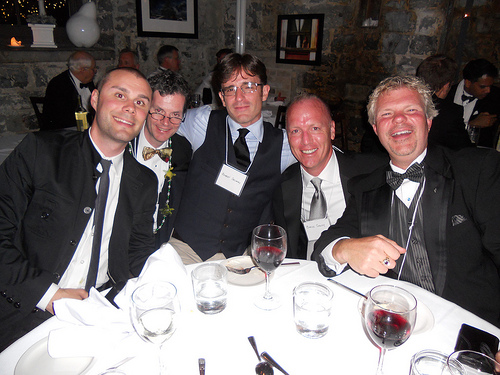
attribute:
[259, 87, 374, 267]
man — balding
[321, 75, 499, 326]
man — smiling,  blonde 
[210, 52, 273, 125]
hair — brown.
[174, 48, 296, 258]
guy — posing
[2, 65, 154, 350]
guy — posing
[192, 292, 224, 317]
liquid — clear.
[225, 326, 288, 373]
spoon — silver.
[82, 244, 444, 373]
table — round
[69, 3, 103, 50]
vase — white.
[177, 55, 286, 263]
man — in center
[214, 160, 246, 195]
tag — name tag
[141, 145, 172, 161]
tie — yellow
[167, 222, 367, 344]
wine glass — empty 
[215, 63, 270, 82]
brown hair — dark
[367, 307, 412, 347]
wine —  red.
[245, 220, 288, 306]
glass — half full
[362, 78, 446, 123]
hair — blonde.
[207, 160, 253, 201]
tag —  white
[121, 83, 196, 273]
guy — posing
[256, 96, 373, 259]
guy — posing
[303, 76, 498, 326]
guy — posing